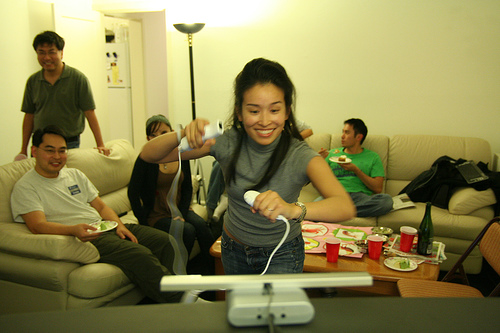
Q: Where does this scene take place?
A: In a living room.